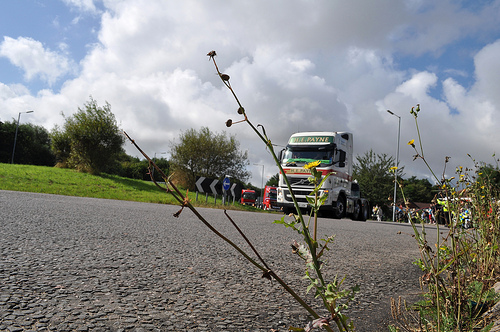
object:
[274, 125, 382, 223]
truck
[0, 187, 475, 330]
road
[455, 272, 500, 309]
weeds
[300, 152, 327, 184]
flowers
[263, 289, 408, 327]
roadside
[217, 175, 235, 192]
sign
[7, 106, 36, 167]
streetlight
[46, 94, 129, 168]
trees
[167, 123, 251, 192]
trees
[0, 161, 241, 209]
hillside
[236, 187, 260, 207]
trucks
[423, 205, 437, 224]
people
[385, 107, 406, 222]
street lamp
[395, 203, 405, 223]
people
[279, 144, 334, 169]
cab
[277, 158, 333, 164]
stripe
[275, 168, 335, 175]
stripe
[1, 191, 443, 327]
concrete